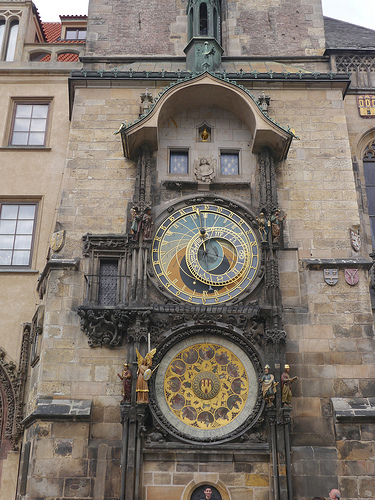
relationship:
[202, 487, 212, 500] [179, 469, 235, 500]
man standing under arch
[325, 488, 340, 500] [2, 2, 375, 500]
man looking at building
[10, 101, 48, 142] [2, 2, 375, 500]
window on building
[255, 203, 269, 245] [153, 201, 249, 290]
statue next to clock face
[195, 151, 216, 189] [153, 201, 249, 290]
statue next to clock face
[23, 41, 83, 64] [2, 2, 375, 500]
balcony on building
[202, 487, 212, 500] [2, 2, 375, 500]
man in front of building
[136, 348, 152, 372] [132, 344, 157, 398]
wings on statue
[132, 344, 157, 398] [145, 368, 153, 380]
statue holding shield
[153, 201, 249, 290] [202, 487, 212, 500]
clock face above man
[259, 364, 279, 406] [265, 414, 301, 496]
statue on a column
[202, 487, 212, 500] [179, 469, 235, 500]
man in arch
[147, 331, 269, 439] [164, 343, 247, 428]
circle with artwork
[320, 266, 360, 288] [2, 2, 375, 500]
shields mounted on building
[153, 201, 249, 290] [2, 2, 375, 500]
clock face on building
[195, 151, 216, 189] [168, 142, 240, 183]
statue between windows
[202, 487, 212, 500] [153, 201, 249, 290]
man standing in front of clock face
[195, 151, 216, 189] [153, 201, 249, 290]
statue on top of clock face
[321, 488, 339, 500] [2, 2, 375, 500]
man looking at building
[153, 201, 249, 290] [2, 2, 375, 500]
clock face on a building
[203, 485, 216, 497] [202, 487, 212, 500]
head of man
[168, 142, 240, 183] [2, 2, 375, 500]
windows on building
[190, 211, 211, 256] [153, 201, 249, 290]
hands on clock face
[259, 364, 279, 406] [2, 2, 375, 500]
statue on building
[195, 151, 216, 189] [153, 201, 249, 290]
statue above clock face